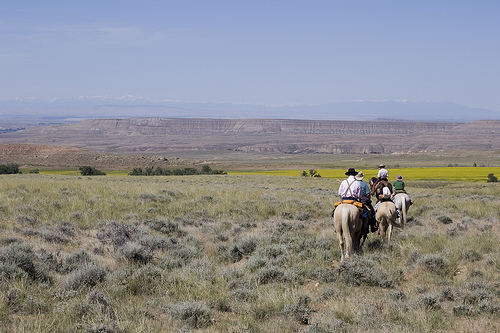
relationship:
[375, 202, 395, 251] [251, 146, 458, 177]
horse on trail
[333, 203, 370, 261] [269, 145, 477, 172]
horse on trail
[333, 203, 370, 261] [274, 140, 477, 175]
horse on trail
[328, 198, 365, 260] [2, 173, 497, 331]
horse on trail